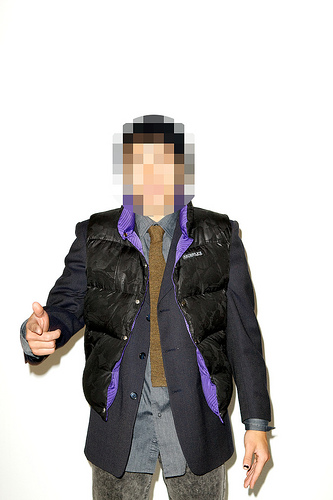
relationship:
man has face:
[20, 113, 274, 499] [129, 142, 174, 212]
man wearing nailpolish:
[20, 113, 274, 499] [241, 460, 250, 470]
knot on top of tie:
[146, 224, 167, 245] [146, 224, 169, 390]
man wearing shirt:
[20, 113, 274, 499] [23, 218, 273, 420]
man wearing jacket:
[20, 113, 274, 499] [27, 216, 272, 419]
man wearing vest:
[20, 113, 274, 499] [83, 199, 232, 422]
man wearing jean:
[20, 113, 274, 499] [88, 456, 225, 500]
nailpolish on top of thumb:
[241, 460, 250, 470] [241, 437, 255, 473]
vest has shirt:
[83, 199, 232, 422] [125, 213, 186, 479]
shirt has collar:
[23, 218, 273, 420] [131, 209, 178, 238]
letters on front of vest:
[179, 249, 204, 261] [83, 199, 232, 422]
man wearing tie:
[20, 113, 274, 499] [146, 224, 169, 390]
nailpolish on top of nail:
[241, 460, 250, 470] [241, 463, 250, 471]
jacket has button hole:
[27, 216, 272, 419] [157, 304, 173, 316]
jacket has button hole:
[27, 216, 272, 419] [163, 343, 180, 359]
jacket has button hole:
[27, 216, 272, 419] [169, 384, 182, 398]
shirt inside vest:
[125, 213, 186, 479] [83, 199, 232, 422]